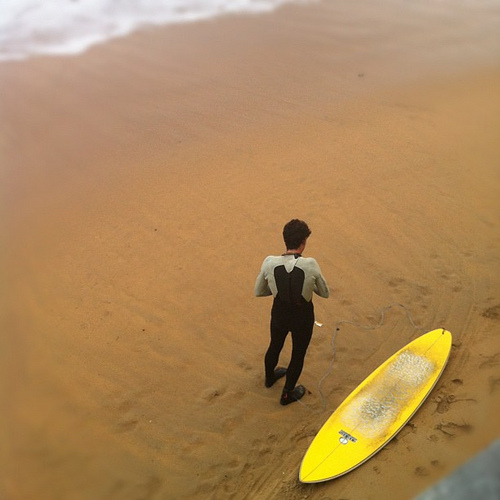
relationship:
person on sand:
[254, 218, 333, 412] [1, 1, 500, 498]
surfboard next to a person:
[298, 327, 453, 484] [254, 218, 333, 412]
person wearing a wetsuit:
[254, 218, 333, 412] [253, 254, 330, 407]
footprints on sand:
[101, 385, 322, 498] [1, 1, 500, 498]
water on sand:
[0, 0, 281, 61] [1, 1, 500, 498]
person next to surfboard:
[254, 218, 333, 412] [298, 327, 453, 484]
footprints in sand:
[101, 385, 322, 498] [1, 1, 500, 498]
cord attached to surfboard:
[300, 297, 451, 401] [298, 327, 453, 484]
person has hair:
[254, 218, 333, 412] [284, 220, 314, 250]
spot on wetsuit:
[283, 391, 291, 401] [253, 254, 330, 407]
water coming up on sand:
[0, 0, 281, 61] [1, 1, 500, 498]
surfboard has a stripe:
[298, 327, 453, 484] [302, 331, 444, 482]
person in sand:
[254, 218, 333, 412] [1, 1, 500, 498]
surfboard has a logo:
[298, 327, 453, 484] [337, 427, 358, 446]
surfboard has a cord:
[298, 327, 453, 484] [300, 297, 451, 401]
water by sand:
[0, 0, 281, 61] [1, 1, 500, 498]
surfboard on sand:
[298, 327, 453, 484] [1, 1, 500, 498]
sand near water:
[1, 1, 500, 498] [0, 0, 281, 61]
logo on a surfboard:
[337, 427, 358, 446] [298, 327, 453, 484]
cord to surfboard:
[300, 297, 451, 401] [298, 327, 453, 484]